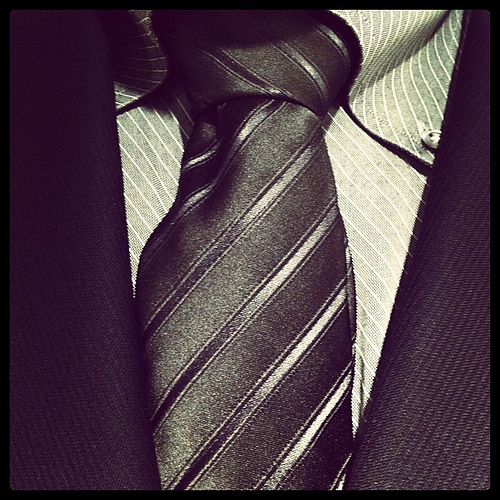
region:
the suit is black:
[403, 425, 421, 451]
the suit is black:
[397, 418, 404, 438]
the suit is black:
[371, 454, 380, 472]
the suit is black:
[404, 444, 419, 469]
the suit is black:
[387, 462, 398, 474]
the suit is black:
[393, 439, 405, 479]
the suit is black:
[412, 434, 418, 458]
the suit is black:
[410, 480, 417, 495]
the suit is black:
[409, 443, 424, 465]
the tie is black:
[230, 450, 243, 470]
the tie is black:
[249, 459, 257, 471]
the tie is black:
[253, 451, 261, 461]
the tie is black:
[229, 454, 238, 476]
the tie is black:
[231, 464, 239, 479]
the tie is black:
[245, 457, 254, 471]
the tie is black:
[270, 232, 277, 248]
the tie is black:
[239, 470, 246, 478]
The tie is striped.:
[146, 60, 383, 472]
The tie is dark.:
[177, 107, 342, 494]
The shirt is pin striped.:
[375, 194, 476, 465]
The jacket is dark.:
[366, 235, 498, 480]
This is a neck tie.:
[143, 14, 385, 479]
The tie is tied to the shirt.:
[104, 1, 387, 469]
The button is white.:
[408, 119, 440, 158]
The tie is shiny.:
[165, 59, 398, 455]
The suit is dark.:
[27, 12, 496, 433]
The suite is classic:
[10, 12, 487, 481]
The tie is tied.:
[145, 22, 368, 477]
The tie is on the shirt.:
[122, 24, 421, 461]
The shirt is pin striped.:
[338, 138, 404, 318]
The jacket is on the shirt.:
[421, 155, 496, 414]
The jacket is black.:
[366, 264, 492, 499]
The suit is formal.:
[29, 13, 482, 487]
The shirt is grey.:
[335, 124, 396, 284]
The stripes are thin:
[156, 118, 396, 499]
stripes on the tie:
[176, 183, 326, 422]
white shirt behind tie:
[361, 211, 388, 262]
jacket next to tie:
[415, 262, 477, 359]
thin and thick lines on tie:
[214, 264, 316, 419]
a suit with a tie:
[23, 18, 440, 390]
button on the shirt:
[381, 25, 458, 223]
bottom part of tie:
[190, 410, 320, 498]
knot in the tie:
[174, 16, 344, 121]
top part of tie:
[167, 123, 334, 229]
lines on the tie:
[127, 109, 177, 159]